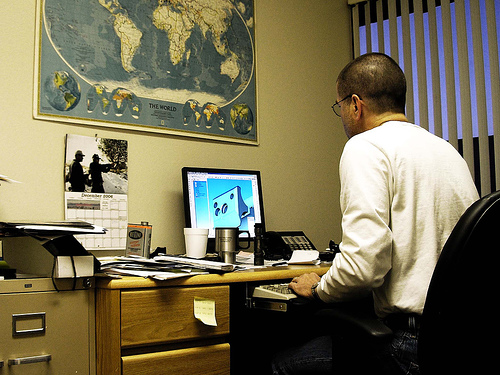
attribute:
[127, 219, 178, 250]
can — metal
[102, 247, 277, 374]
desk — wooded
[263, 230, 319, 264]
telephone — black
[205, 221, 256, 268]
cup — stainless steel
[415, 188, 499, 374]
chair — black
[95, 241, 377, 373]
desk — light brown, wooden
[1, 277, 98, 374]
cabinet — tan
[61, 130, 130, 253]
calendar — white, black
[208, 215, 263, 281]
mug — travel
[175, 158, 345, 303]
computer — sitting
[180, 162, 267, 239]
monitor — black, flat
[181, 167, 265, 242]
monitor — black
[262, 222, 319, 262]
phone — black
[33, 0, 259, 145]
map — hanging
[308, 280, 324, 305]
watch — wrist watch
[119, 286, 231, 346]
drawer — wood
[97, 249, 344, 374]
desk — wooden, brown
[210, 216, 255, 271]
cup — silver, black, metal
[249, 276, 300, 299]
keyboard — used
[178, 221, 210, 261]
cup — white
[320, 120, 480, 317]
shirt — white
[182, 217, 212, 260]
cup — white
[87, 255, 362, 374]
desk — wooden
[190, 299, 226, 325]
sticky note — yellow